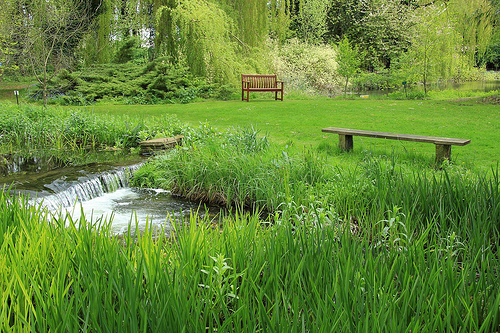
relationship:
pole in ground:
[12, 96, 39, 110] [43, 92, 62, 109]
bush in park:
[286, 55, 330, 88] [80, 15, 428, 326]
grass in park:
[276, 204, 419, 319] [44, 72, 446, 321]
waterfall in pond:
[74, 178, 114, 199] [56, 156, 196, 228]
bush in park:
[345, 4, 466, 100] [13, 18, 453, 310]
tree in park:
[42, 9, 86, 98] [2, 3, 476, 314]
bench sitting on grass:
[214, 70, 284, 102] [235, 98, 273, 118]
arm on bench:
[241, 69, 253, 87] [238, 74, 317, 98]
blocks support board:
[415, 145, 453, 174] [347, 117, 396, 141]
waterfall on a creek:
[74, 178, 114, 199] [41, 155, 158, 225]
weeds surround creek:
[314, 147, 465, 307] [115, 122, 218, 236]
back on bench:
[240, 78, 278, 90] [232, 68, 292, 103]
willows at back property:
[175, 11, 224, 79] [101, 19, 471, 328]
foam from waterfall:
[85, 198, 115, 226] [27, 159, 147, 229]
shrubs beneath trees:
[26, 61, 207, 111] [7, 1, 345, 90]